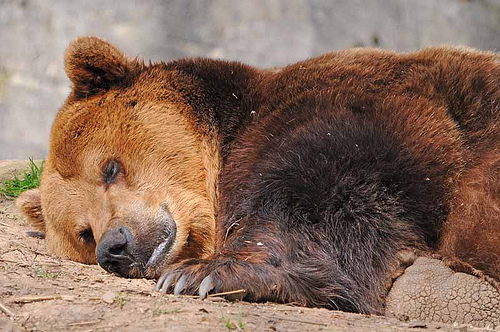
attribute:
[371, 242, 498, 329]
paw — bear's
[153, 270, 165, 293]
claws — gray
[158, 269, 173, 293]
claws — gray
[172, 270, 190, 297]
claws — gray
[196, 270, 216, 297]
claws — gray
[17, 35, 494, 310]
bear — brown, lying down, black, large, fuzzy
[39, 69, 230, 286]
head — brown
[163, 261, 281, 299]
claws — bear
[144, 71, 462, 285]
fur — light, dark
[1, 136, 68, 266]
grass — green, small, patch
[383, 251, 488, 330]
paw — bear's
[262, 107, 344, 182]
fur — bear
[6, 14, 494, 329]
background — gray, blurred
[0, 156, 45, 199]
grass — green, behind, patch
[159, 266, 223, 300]
claws — sharp, grey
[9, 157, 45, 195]
grass — small, green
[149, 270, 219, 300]
claws — four, grey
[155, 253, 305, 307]
hand — bear's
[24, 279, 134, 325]
ground — part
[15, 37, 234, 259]
head — bears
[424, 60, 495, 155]
brown spot — dark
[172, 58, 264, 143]
brown spot — dark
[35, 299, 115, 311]
ground — part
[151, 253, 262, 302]
paw — edge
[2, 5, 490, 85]
background — blurred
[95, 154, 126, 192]
eye — open , one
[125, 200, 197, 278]
mouth — part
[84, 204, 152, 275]
nose — black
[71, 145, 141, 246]
eyes — bear's, closed